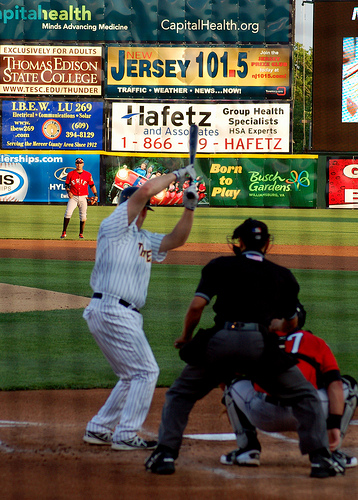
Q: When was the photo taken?
A: Daytime.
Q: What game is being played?
A: Baseball.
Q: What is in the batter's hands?
A: Bat.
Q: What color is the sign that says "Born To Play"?
A: Green.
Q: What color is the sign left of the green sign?
A: Blue.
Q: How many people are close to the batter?
A: Two.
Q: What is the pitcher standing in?
A: Grass.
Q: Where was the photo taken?
A: At a baseball game.